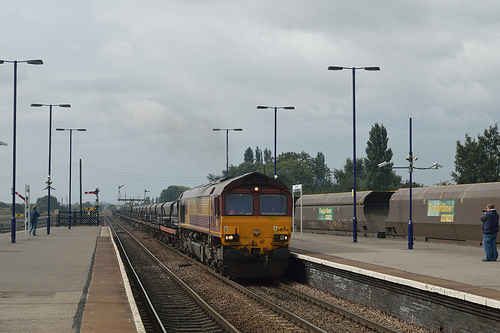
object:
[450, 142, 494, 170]
leaves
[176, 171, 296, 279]
cart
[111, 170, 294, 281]
train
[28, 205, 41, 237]
person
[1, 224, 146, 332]
platform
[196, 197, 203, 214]
label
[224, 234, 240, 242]
lights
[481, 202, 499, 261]
man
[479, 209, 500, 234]
jacket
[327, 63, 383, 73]
lights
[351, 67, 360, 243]
pole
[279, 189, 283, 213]
windshield wiper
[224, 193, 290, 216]
windshield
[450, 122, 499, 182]
tree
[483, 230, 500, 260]
jeans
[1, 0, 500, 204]
sky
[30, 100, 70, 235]
street lamp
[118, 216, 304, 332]
rocks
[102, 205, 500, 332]
train tracks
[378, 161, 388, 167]
security camera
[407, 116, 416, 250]
pole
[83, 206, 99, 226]
stand